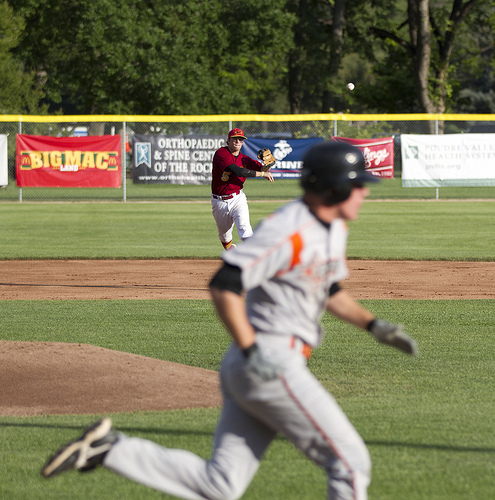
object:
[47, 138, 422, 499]
player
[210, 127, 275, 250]
player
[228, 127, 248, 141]
cap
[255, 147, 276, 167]
glove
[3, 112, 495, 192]
barrier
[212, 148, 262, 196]
shirt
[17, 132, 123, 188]
ad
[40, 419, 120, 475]
sneaker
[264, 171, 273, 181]
hand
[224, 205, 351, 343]
jersey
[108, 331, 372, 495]
pants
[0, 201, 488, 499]
field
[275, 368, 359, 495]
pinstripe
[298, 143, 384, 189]
helmet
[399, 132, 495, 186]
banner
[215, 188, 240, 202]
belt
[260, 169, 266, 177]
waist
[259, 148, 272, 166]
hand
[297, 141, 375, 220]
head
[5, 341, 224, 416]
mound